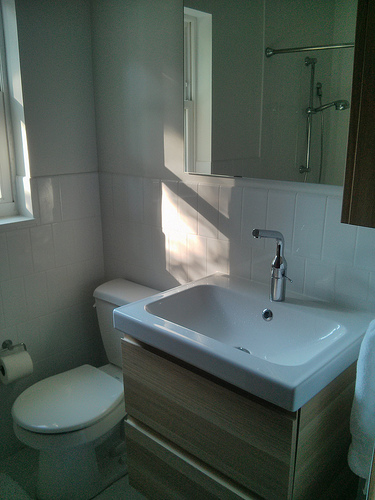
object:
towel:
[347, 320, 372, 481]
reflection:
[184, 3, 357, 186]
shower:
[298, 53, 352, 182]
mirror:
[175, 7, 352, 185]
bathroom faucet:
[250, 225, 294, 304]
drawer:
[119, 336, 296, 498]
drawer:
[118, 416, 251, 498]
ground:
[260, 115, 285, 153]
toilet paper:
[0, 345, 36, 387]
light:
[157, 113, 234, 286]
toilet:
[9, 273, 169, 498]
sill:
[1, 201, 34, 223]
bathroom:
[4, 0, 370, 498]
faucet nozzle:
[251, 230, 262, 239]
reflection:
[308, 89, 350, 119]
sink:
[107, 271, 373, 394]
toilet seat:
[7, 363, 125, 433]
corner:
[57, 3, 137, 393]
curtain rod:
[265, 43, 353, 59]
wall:
[46, 0, 176, 263]